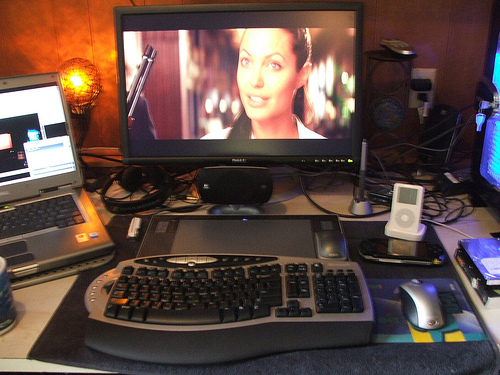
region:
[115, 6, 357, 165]
movie playing on computer monitor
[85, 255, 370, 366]
black and silver computer keyboard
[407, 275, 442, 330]
black and silver wireless mouse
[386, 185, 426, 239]
iPod docked in charger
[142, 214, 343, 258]
computer drawing tablet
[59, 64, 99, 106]
orange glowing light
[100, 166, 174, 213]
black headphones under monitor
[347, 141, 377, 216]
silver and black microphone to right of monitor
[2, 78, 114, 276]
small laptop on left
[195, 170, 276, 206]
center speaker under monitor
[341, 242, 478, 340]
an optical mouse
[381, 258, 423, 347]
an optical mouse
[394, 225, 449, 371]
an optical mouse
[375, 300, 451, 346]
an optical mouse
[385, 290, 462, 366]
an optical mouse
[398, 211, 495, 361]
an optical mouse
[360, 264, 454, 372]
an optical mouse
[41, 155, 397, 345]
the keyboard is black and grey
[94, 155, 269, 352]
the keyboard is black and grey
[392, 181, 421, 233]
white ipod mp3 player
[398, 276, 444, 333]
blue and silver cordless mouse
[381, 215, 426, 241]
small white mp3 player dock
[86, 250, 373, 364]
independent desktop computer keyboard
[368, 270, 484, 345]
multi-colored mouse pad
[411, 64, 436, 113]
electric wall outlet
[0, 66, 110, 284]
silver laptop with black keyboard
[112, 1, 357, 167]
large screen computer monitor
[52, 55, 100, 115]
opaque orange wall light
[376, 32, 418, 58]
television remote control